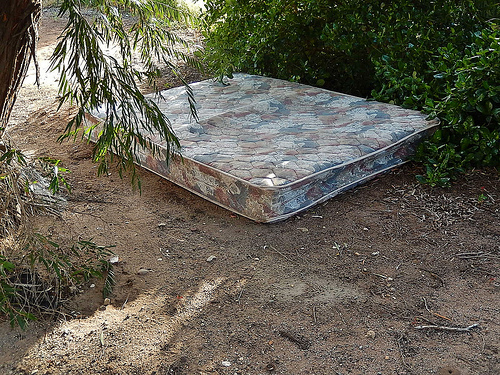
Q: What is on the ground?
A: The mattress.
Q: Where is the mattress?
A: Under the tree.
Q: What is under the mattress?
A: The sandy ground.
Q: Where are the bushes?
A: Next to the mattress.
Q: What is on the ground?
A: A mattress.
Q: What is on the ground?
A: Dirt.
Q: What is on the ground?
A: Dirt.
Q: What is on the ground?
A: Dirt.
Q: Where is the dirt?
A: On the ground.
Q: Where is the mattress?
A: On the ground.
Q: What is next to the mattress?
A: A tree.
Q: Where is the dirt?
A: On the ground.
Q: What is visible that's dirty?
A: The mattress.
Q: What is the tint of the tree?
A: Green.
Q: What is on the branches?
A: Leaves.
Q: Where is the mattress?
A: On the dirt.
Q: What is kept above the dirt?
A: Multi color mattress.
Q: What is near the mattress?
A: Dirt.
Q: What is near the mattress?
A: A tree.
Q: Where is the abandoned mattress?
A: On the ground.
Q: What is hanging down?
A: Tree branch and leaves.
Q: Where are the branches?
A: On the ground.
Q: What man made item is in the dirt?
A: A mattress.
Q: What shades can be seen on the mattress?
A: Blue, white and light red.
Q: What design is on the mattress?
A: A floral design.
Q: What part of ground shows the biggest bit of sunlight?
A: The area behind the mattress.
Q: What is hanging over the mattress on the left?
A: Thin leaves on a branch.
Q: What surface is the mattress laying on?
A: Dirt.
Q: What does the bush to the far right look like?
A: Green and lush.